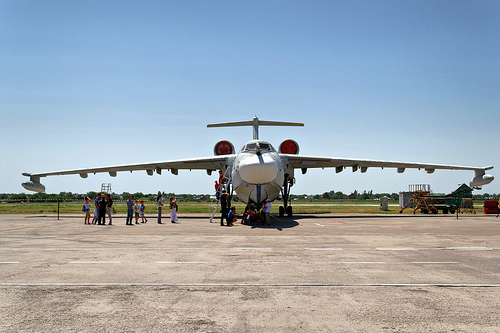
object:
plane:
[21, 116, 495, 225]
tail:
[207, 115, 305, 141]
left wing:
[279, 152, 495, 189]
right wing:
[25, 154, 234, 192]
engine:
[215, 142, 233, 155]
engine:
[281, 139, 298, 154]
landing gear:
[216, 173, 293, 222]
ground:
[0, 213, 499, 333]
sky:
[0, 1, 500, 197]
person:
[169, 196, 179, 223]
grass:
[1, 200, 499, 216]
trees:
[1, 189, 499, 202]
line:
[0, 282, 499, 289]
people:
[126, 195, 148, 225]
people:
[81, 193, 113, 225]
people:
[214, 170, 224, 200]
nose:
[239, 154, 280, 184]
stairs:
[209, 164, 234, 223]